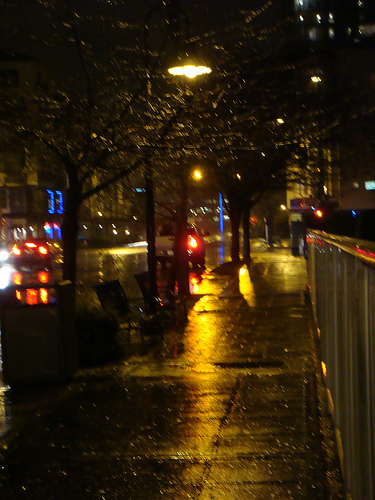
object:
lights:
[37, 171, 74, 230]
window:
[23, 154, 104, 261]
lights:
[176, 235, 214, 284]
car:
[136, 213, 236, 285]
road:
[28, 216, 319, 455]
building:
[3, 80, 233, 300]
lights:
[24, 157, 121, 279]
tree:
[74, 8, 177, 325]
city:
[0, 0, 373, 488]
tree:
[197, 3, 308, 266]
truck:
[150, 218, 205, 271]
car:
[7, 236, 61, 268]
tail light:
[186, 233, 203, 249]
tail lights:
[7, 241, 46, 257]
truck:
[3, 226, 71, 266]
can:
[125, 262, 166, 310]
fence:
[301, 224, 373, 500]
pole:
[168, 173, 189, 314]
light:
[191, 167, 203, 182]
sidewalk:
[32, 251, 335, 469]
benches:
[89, 264, 163, 323]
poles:
[136, 171, 164, 303]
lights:
[37, 246, 51, 247]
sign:
[44, 186, 56, 208]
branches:
[92, 129, 115, 150]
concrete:
[40, 254, 333, 500]